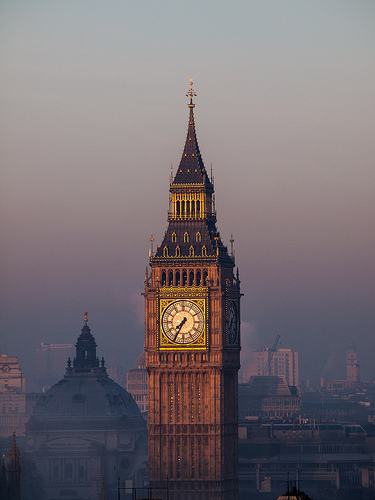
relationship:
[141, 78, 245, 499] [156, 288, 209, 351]
architecture has a clock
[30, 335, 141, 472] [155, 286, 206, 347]
building next to clock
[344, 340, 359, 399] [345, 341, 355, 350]
building with dome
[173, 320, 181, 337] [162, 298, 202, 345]
hand of clock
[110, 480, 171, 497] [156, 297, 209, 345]
gate on clock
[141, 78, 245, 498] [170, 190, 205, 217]
ornatetower, has accents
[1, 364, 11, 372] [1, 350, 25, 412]
clock on building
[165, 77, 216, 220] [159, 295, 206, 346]
steeple with clock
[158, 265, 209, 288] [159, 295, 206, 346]
windows above clock